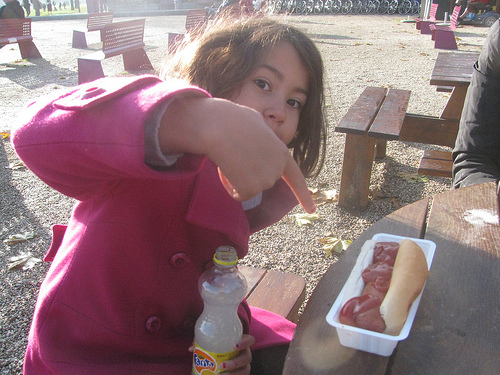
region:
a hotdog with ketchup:
[325, 224, 432, 360]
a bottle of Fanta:
[182, 238, 259, 374]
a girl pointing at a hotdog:
[105, 6, 447, 355]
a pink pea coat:
[10, 65, 255, 371]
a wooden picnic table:
[339, 33, 464, 192]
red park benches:
[52, 3, 172, 74]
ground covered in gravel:
[338, 30, 428, 85]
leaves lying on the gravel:
[0, 228, 47, 275]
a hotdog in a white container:
[323, 214, 441, 361]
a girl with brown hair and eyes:
[157, 10, 350, 172]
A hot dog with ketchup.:
[348, 236, 420, 341]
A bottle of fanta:
[194, 245, 246, 374]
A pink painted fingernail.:
[219, 360, 226, 370]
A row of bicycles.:
[270, 0, 417, 15]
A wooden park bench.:
[336, 50, 483, 210]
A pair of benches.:
[414, 2, 461, 51]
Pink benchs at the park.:
[70, 13, 165, 85]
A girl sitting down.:
[1, 0, 333, 373]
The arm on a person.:
[450, 16, 498, 188]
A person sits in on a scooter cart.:
[456, 0, 498, 28]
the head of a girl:
[161, 9, 327, 164]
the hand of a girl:
[191, 90, 321, 218]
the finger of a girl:
[279, 152, 321, 218]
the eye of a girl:
[248, 73, 274, 96]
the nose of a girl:
[261, 88, 293, 125]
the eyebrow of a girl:
[256, 57, 286, 79]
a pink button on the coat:
[166, 247, 191, 272]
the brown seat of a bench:
[328, 75, 413, 147]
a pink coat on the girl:
[1, 75, 299, 374]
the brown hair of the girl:
[150, 14, 334, 186]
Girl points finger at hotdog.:
[271, 131, 331, 221]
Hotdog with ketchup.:
[349, 237, 384, 322]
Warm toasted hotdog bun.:
[396, 236, 431, 339]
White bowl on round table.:
[325, 326, 404, 359]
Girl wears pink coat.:
[61, 88, 201, 333]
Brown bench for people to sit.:
[338, 76, 413, 155]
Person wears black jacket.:
[441, 44, 498, 193]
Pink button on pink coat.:
[163, 233, 193, 288]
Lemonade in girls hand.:
[183, 241, 258, 373]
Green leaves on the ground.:
[291, 213, 348, 254]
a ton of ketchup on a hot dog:
[340, 232, 398, 329]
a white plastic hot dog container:
[325, 230, 431, 352]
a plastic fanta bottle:
[196, 239, 258, 371]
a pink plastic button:
[171, 252, 187, 266]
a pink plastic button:
[142, 315, 158, 331]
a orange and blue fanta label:
[190, 348, 217, 372]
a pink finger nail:
[220, 358, 228, 366]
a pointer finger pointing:
[279, 155, 317, 212]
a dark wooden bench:
[235, 254, 299, 321]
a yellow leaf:
[323, 230, 348, 254]